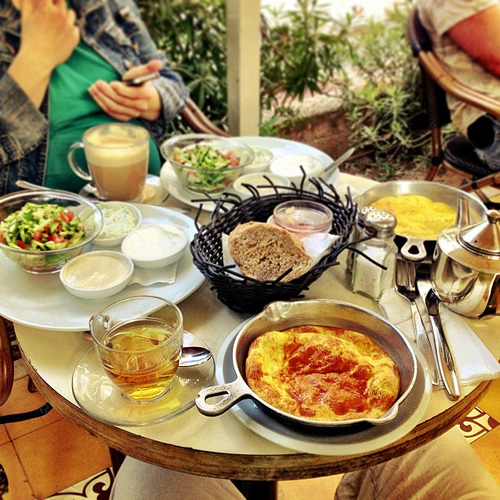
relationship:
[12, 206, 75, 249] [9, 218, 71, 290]
salad in a bowl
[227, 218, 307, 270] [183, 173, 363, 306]
bread in basket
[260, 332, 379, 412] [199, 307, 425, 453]
omellette in a skillet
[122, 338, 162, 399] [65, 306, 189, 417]
tea in a cup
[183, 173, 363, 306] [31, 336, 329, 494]
basket on table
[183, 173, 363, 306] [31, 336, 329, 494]
basket in a table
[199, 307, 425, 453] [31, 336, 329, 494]
skillet on table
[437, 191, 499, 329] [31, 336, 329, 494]
kettle on table